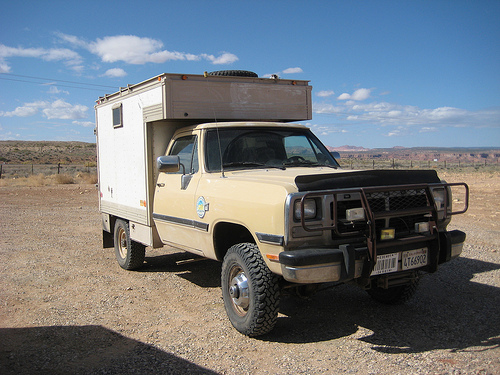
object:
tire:
[205, 68, 260, 78]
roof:
[91, 72, 314, 121]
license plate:
[401, 247, 430, 271]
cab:
[93, 70, 470, 337]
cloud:
[85, 32, 200, 68]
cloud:
[0, 42, 89, 78]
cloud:
[100, 67, 129, 79]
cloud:
[282, 65, 304, 75]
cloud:
[209, 51, 239, 67]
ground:
[0, 164, 500, 375]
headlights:
[429, 188, 449, 209]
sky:
[0, 0, 500, 145]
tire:
[216, 239, 282, 340]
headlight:
[292, 198, 319, 222]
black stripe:
[153, 212, 208, 232]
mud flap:
[100, 212, 117, 249]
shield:
[196, 126, 343, 173]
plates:
[365, 252, 400, 276]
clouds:
[334, 87, 375, 102]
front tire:
[214, 241, 287, 338]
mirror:
[156, 155, 180, 172]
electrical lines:
[0, 71, 116, 89]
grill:
[328, 187, 434, 245]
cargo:
[92, 74, 317, 250]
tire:
[110, 214, 148, 271]